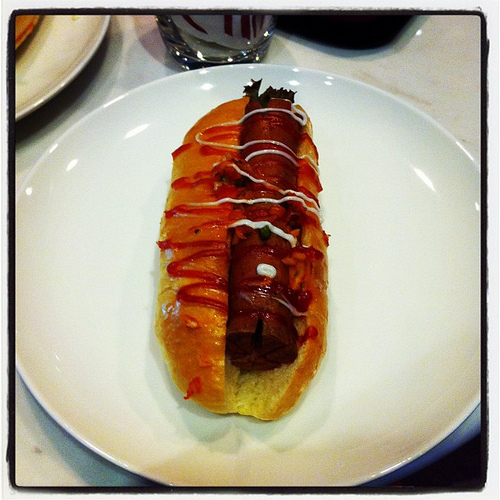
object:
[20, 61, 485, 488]
plate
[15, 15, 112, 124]
plate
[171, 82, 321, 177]
portion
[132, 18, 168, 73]
shadow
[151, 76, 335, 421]
bun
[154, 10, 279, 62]
glass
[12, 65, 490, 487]
white plate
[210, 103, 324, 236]
mayonaise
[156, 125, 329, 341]
ketchup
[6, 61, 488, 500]
plate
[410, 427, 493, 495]
shadow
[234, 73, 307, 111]
lettuce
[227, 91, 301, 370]
dog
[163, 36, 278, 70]
bottom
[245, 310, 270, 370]
cuts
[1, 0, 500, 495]
table